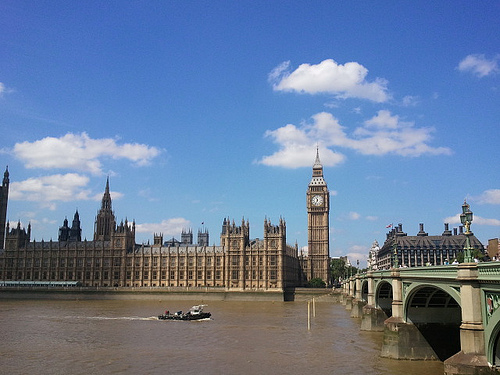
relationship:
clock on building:
[313, 197, 324, 207] [0, 141, 331, 290]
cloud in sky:
[0, 52, 499, 271] [1, 1, 499, 270]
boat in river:
[157, 306, 210, 321] [1, 298, 460, 375]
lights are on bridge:
[459, 203, 473, 225] [340, 264, 500, 373]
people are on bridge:
[396, 259, 463, 266] [340, 264, 500, 373]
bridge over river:
[340, 264, 500, 373] [1, 298, 460, 375]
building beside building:
[0, 141, 331, 290] [1, 218, 304, 289]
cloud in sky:
[256, 112, 454, 170] [1, 1, 499, 270]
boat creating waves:
[157, 306, 210, 321] [64, 317, 157, 323]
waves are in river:
[64, 317, 157, 323] [1, 298, 460, 375]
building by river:
[1, 218, 304, 289] [1, 298, 460, 375]